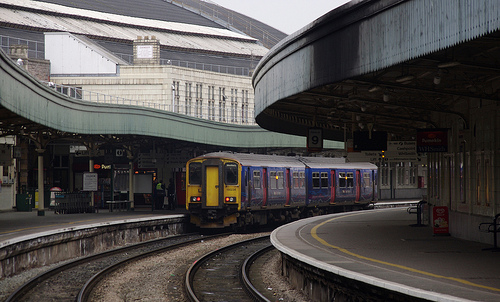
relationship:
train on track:
[181, 149, 381, 231] [6, 226, 236, 301]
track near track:
[6, 226, 236, 301] [185, 232, 281, 301]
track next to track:
[6, 226, 236, 301] [185, 232, 281, 301]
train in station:
[181, 149, 381, 231] [3, 1, 500, 298]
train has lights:
[181, 149, 381, 231] [222, 194, 238, 205]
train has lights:
[181, 149, 381, 231] [187, 193, 204, 204]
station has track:
[3, 1, 500, 298] [6, 226, 236, 301]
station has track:
[3, 1, 500, 298] [185, 232, 281, 301]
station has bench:
[3, 1, 500, 298] [405, 197, 429, 227]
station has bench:
[3, 1, 500, 298] [52, 190, 101, 214]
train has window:
[181, 149, 381, 231] [185, 160, 204, 187]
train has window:
[181, 149, 381, 231] [222, 160, 242, 189]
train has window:
[181, 149, 381, 231] [310, 171, 330, 189]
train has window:
[181, 149, 381, 231] [338, 171, 356, 189]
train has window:
[181, 149, 381, 231] [265, 168, 286, 193]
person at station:
[164, 178, 179, 211] [3, 1, 500, 298]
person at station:
[155, 177, 166, 214] [3, 1, 500, 298]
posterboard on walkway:
[432, 206, 450, 236] [273, 204, 500, 302]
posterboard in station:
[432, 206, 450, 236] [3, 1, 500, 298]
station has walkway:
[3, 1, 500, 298] [273, 204, 500, 302]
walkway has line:
[273, 204, 500, 302] [308, 206, 498, 299]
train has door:
[181, 149, 381, 231] [326, 167, 338, 201]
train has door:
[181, 149, 381, 231] [350, 166, 364, 207]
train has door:
[181, 149, 381, 231] [283, 167, 293, 207]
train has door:
[181, 149, 381, 231] [259, 163, 270, 211]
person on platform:
[164, 178, 179, 211] [0, 205, 189, 282]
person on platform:
[155, 177, 166, 214] [0, 205, 189, 282]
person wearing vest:
[155, 177, 166, 214] [154, 181, 163, 192]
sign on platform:
[92, 156, 117, 178] [0, 205, 189, 282]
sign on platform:
[80, 168, 102, 193] [0, 205, 189, 282]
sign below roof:
[92, 156, 117, 178] [0, 49, 345, 149]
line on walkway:
[308, 206, 498, 299] [273, 204, 500, 302]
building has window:
[50, 65, 257, 122] [169, 76, 183, 116]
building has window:
[50, 65, 257, 122] [182, 76, 195, 115]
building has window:
[50, 65, 257, 122] [194, 79, 205, 116]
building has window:
[50, 65, 257, 122] [206, 81, 219, 121]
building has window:
[50, 65, 257, 122] [217, 85, 228, 124]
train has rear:
[181, 149, 381, 231] [302, 154, 381, 210]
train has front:
[181, 149, 381, 231] [185, 151, 308, 226]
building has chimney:
[50, 65, 257, 122] [130, 34, 162, 64]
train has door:
[181, 149, 381, 231] [203, 165, 222, 207]